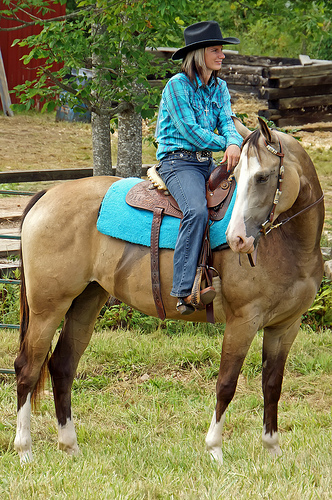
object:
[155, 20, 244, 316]
woman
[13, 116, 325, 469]
horse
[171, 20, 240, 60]
hat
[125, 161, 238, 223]
saddle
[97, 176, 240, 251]
blue banket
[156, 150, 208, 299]
jeans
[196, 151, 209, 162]
silver buckle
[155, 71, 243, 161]
blue shirt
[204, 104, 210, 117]
cross necklace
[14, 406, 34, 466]
white stocking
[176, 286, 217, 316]
brown boot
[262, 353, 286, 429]
black markings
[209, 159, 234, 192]
saddle strap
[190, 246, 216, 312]
stirrup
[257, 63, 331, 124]
wooden fence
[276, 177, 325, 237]
bridle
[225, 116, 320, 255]
head turned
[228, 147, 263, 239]
white markings